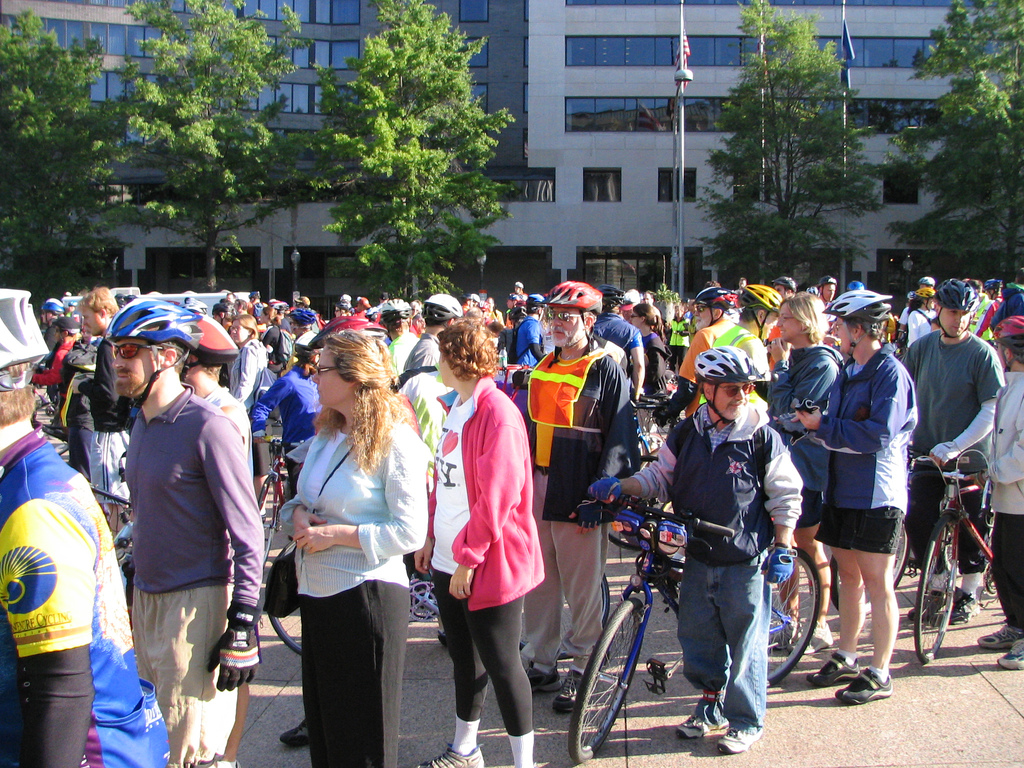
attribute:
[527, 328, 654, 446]
vest — yellow, orange, safety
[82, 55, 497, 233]
trees — tall, green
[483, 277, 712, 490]
helmet — red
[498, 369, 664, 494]
vest — orange, yellow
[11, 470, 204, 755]
vest — blue, yellow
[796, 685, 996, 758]
sidewalk — dark tan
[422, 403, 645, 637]
shirt — pink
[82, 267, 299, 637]
helmet — blue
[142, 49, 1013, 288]
trees — green, tall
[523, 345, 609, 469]
vest — orange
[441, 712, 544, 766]
socks — white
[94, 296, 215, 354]
helmet — blue, silver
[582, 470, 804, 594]
gloves — black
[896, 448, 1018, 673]
bicycle — red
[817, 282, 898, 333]
helmet — black, white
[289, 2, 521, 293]
trees — green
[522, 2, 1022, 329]
building — tall, white, gray, office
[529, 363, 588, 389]
stripe — yellow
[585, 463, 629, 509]
gloves — blue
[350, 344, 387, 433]
hair — long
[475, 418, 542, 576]
coat — pink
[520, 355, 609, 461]
vest — safety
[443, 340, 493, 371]
hair — red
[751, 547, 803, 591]
gloves — blue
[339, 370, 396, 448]
hair — long, blonde